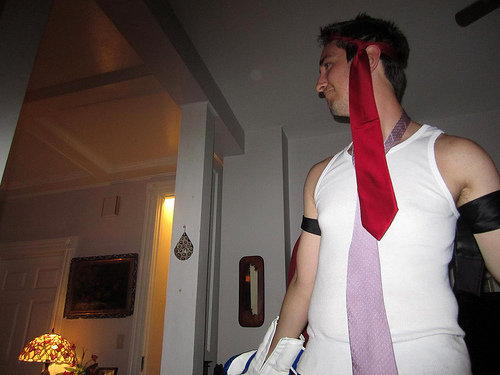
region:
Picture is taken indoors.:
[29, 19, 486, 354]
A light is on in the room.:
[144, 180, 176, 305]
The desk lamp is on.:
[22, 319, 97, 361]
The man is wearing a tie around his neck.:
[310, 87, 432, 207]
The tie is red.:
[357, 165, 412, 267]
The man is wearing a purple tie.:
[332, 147, 387, 370]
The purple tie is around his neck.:
[329, 130, 391, 295]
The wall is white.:
[257, 102, 277, 209]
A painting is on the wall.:
[35, 237, 140, 326]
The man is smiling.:
[312, 40, 424, 117]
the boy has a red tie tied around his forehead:
[312, 15, 409, 240]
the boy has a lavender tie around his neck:
[308, 111, 419, 371]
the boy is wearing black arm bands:
[298, 180, 498, 243]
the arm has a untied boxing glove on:
[216, 308, 308, 370]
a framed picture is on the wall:
[60, 247, 140, 322]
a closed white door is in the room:
[1, 230, 76, 371]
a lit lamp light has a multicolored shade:
[15, 321, 80, 371]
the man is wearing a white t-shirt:
[302, 120, 464, 340]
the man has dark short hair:
[310, 11, 410, 116]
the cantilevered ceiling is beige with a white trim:
[8, 115, 183, 196]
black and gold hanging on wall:
[168, 220, 205, 267]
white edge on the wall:
[159, 120, 231, 182]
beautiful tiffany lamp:
[12, 330, 92, 365]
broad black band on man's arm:
[278, 205, 338, 242]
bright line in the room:
[135, 163, 207, 241]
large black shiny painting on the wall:
[37, 236, 159, 328]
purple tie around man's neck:
[338, 261, 426, 355]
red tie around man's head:
[315, 20, 407, 233]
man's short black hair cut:
[309, 16, 432, 91]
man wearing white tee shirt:
[295, 124, 468, 359]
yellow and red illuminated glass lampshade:
[11, 323, 83, 371]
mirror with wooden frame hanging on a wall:
[230, 246, 270, 333]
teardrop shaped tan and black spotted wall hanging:
[171, 224, 196, 266]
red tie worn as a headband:
[323, 32, 424, 239]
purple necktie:
[341, 107, 416, 373]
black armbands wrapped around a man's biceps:
[287, 184, 498, 247]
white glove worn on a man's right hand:
[210, 311, 307, 373]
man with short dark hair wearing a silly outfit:
[223, 8, 498, 373]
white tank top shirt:
[309, 121, 469, 340]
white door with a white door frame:
[0, 226, 75, 373]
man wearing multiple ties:
[277, 12, 498, 372]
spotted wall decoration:
[173, 224, 195, 262]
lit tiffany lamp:
[18, 328, 85, 374]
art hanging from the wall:
[61, 249, 141, 324]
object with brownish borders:
[231, 248, 269, 328]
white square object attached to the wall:
[91, 191, 128, 223]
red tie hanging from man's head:
[316, 16, 409, 240]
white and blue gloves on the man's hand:
[234, 309, 318, 374]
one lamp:
[12, 319, 90, 374]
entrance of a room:
[136, 173, 175, 373]